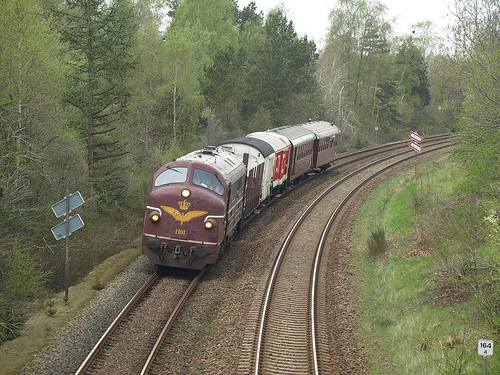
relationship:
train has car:
[140, 120, 337, 272] [138, 142, 243, 281]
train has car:
[140, 120, 337, 272] [299, 107, 337, 179]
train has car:
[140, 120, 337, 272] [268, 121, 315, 187]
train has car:
[140, 120, 337, 272] [219, 137, 267, 221]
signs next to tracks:
[411, 127, 421, 156] [245, 141, 391, 372]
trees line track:
[1, 0, 497, 345] [74, 130, 460, 375]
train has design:
[140, 120, 337, 272] [161, 200, 208, 237]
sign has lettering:
[472, 334, 498, 359] [477, 340, 493, 349]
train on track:
[140, 120, 337, 272] [74, 130, 459, 373]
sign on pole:
[47, 188, 90, 245] [60, 189, 71, 299]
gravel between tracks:
[148, 138, 411, 373] [75, 120, 457, 370]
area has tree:
[8, 1, 492, 318] [49, 0, 143, 212]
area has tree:
[8, 1, 492, 318] [138, 65, 204, 158]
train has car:
[140, 120, 337, 272] [296, 120, 341, 170]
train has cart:
[140, 120, 337, 272] [244, 129, 291, 188]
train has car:
[140, 120, 337, 272] [217, 128, 293, 220]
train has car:
[140, 120, 337, 272] [140, 145, 247, 273]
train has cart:
[141, 120, 356, 259] [115, 149, 261, 259]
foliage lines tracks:
[357, 0, 497, 372] [75, 120, 457, 370]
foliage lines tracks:
[0, 0, 433, 372] [75, 120, 457, 370]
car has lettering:
[226, 128, 296, 201] [269, 152, 289, 181]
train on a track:
[140, 120, 337, 272] [74, 270, 206, 374]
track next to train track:
[237, 137, 462, 375] [63, 110, 454, 373]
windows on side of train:
[293, 140, 315, 158] [140, 120, 337, 272]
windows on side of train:
[317, 133, 337, 148] [140, 120, 337, 272]